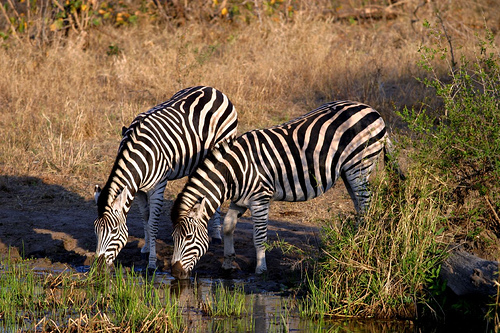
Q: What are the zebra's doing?
A: Drinking water.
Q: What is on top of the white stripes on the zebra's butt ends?
A: Thin rust stripes.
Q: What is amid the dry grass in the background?
A: Yellowing leaves.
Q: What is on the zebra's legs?
A: Small, thin stripes.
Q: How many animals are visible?
A: Two.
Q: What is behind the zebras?
A: Dead grass.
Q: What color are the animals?
A: Black and white.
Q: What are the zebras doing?
A: Drinking water.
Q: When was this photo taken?
A: In the afternoon.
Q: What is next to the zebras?
A: Tall weeds.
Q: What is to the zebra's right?
A: Long shadows.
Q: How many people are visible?
A: None.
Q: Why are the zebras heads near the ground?
A: To drink.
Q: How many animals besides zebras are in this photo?
A: 0.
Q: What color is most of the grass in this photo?
A: Brown.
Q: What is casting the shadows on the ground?
A: The zebras.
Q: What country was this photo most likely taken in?
A: Africa.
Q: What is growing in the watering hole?
A: Grasses.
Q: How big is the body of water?
A: Small.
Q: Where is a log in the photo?
A: Bottom right by water.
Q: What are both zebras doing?
A: Drinking water.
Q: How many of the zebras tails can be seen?
A: 1.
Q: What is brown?
A: The field.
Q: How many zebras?
A: Two.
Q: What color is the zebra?
A: Black and white.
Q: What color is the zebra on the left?
A: Black and white.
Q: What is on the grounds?
A: Water.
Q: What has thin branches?
A: The bush.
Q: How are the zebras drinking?
A: With their heads bent to the water.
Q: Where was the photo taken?
A: Outside, near a small body of water.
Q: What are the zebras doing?
A: Drinking.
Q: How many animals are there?
A: Two.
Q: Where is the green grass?
A: Near the water.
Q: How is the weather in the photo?
A: Sunny.